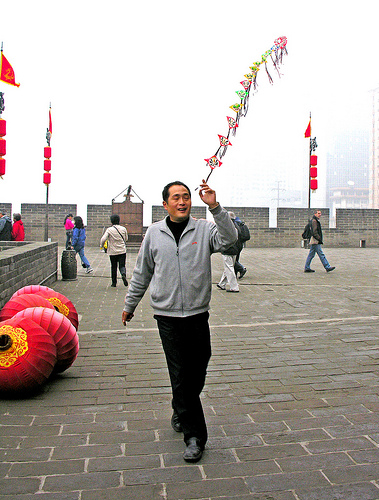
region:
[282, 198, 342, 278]
this man has a backpack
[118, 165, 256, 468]
he is wearing a grey sweater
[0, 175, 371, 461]
people on the Great Wall of China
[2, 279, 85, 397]
these are large paper lanterns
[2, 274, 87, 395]
red Chinese lanterns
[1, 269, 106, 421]
a line of red lanterns on the ground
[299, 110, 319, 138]
this is a red flag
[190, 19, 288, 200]
this is a long kite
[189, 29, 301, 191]
there are many kites tied together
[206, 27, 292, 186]
a collection of colorful kites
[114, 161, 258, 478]
man with his eyes closed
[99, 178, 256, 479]
man wearing grey zip up jacket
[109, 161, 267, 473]
man gesturing upward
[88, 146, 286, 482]
man walking on brick building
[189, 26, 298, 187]
colorful decoration in the wind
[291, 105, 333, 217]
flags and decorations on pole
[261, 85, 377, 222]
buildings visible through the mist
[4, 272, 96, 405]
red decorative paper lantern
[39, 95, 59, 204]
flags and lanterns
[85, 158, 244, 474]
man wearing black shoes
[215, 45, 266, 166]
kites in sky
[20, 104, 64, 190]
flags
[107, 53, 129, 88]
white clouds in blue sky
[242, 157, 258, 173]
white clouds in blue sky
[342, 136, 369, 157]
white clouds in blue sky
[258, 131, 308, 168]
white clouds in blue sky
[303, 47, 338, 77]
white clouds in blue sky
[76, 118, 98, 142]
white clouds in blue sky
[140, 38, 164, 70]
white clouds in blue sky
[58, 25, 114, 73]
white clouds in blue sky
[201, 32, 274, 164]
kites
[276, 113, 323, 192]
kites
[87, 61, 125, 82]
white clouds in blue sky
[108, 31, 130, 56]
white clouds in blue sky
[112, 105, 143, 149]
white clouds in blue sky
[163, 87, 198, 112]
white clouds in blue sky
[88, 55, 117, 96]
white clouds in blue sky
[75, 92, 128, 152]
white clouds in blue sky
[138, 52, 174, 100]
white clouds in blue sky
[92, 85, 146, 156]
white clouds in blue sky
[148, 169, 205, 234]
head of a man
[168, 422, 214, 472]
shoe on man's foot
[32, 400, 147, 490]
lines on the ground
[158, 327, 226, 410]
black pants on man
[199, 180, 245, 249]
arm of the man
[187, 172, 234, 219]
hand of the man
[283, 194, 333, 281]
person in the background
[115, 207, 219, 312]
gray sweater on man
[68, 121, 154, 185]
sky above the land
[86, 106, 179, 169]
white sky in photo